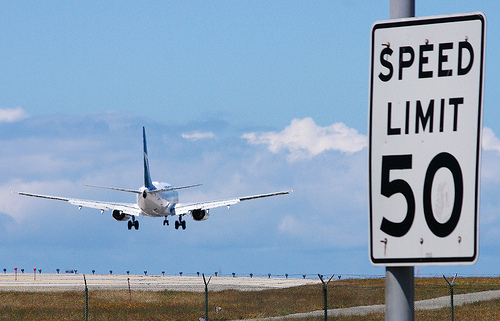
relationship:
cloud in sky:
[259, 116, 371, 153] [3, 2, 369, 106]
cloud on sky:
[481, 125, 499, 199] [3, 2, 369, 106]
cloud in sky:
[1, 106, 30, 125] [3, 2, 369, 106]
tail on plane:
[142, 125, 153, 189] [11, 126, 293, 231]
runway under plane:
[1, 275, 314, 292] [11, 126, 293, 231]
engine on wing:
[192, 208, 209, 222] [176, 191, 294, 218]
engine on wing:
[112, 211, 130, 221] [12, 190, 139, 216]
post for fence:
[84, 276, 89, 321] [0, 273, 388, 321]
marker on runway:
[15, 265, 21, 281] [1, 275, 314, 292]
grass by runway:
[3, 291, 249, 321] [1, 275, 314, 292]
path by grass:
[326, 303, 383, 318] [3, 291, 249, 321]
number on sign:
[379, 153, 464, 238] [367, 13, 485, 264]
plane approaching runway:
[11, 126, 293, 231] [1, 275, 314, 292]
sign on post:
[367, 13, 485, 264] [84, 276, 89, 321]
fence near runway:
[0, 273, 388, 321] [1, 275, 314, 292]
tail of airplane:
[142, 125, 153, 189] [11, 126, 293, 231]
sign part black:
[367, 13, 485, 264] [439, 18, 478, 21]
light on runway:
[34, 267, 38, 281] [1, 275, 314, 292]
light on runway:
[56, 268, 61, 276] [1, 275, 314, 292]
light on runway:
[110, 269, 114, 275] [1, 275, 314, 292]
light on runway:
[144, 269, 147, 277] [1, 275, 314, 292]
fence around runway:
[0, 273, 388, 321] [1, 275, 314, 292]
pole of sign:
[386, 266, 415, 320] [367, 13, 485, 264]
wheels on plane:
[128, 219, 139, 231] [11, 126, 293, 231]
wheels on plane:
[175, 219, 186, 230] [11, 126, 293, 231]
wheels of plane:
[162, 219, 169, 225] [11, 126, 293, 231]